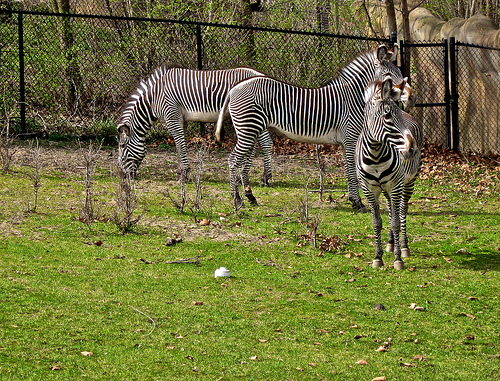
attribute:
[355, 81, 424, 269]
zebra — grazing, eye, compact, black, standing, eating, distracted, little, three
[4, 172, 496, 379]
grass — green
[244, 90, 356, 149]
stripes — white, straight, black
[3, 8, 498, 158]
fence — black, large, chain link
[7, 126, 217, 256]
plant — brown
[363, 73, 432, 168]
head — angled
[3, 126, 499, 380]
ground — small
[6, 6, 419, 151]
leaves — small, smattered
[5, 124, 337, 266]
bushes — dead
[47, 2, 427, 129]
trees — narrow, beyond